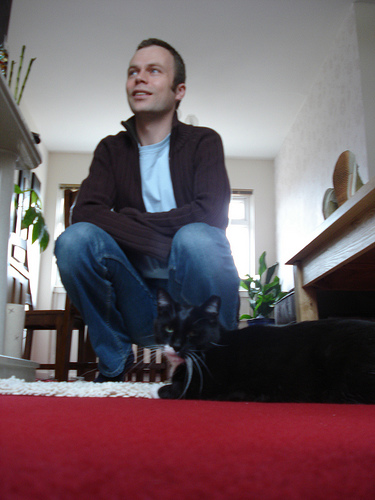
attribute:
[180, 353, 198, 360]
spot — small white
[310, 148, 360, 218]
plates — some decorative 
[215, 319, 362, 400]
body —  primarily black , cats 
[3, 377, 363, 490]
floor — red 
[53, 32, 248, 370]
man — looking 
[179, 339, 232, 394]
whiskers — white 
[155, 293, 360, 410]
cat — black 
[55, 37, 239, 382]
guy — squatting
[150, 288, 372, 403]
cat — black, white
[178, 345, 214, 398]
whiskers — white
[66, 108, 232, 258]
sweater — brown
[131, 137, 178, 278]
shirt — white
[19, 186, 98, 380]
chair — brown, wooden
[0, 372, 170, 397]
cloth — white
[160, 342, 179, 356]
patch — white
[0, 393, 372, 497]
carpet — red, bright red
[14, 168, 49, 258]
plant — green, hanging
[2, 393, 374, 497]
rug — red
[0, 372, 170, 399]
rug — fluffy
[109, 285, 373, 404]
cat — black, white, big, ugly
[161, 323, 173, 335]
eye — big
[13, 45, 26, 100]
bamboo — green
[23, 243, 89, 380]
chair — dark colored, wood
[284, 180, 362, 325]
table — wood, light colored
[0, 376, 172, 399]
rug — high pile, white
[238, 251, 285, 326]
plant — large leafed, potted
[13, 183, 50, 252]
plant — green, leafy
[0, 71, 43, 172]
mantle — large, white